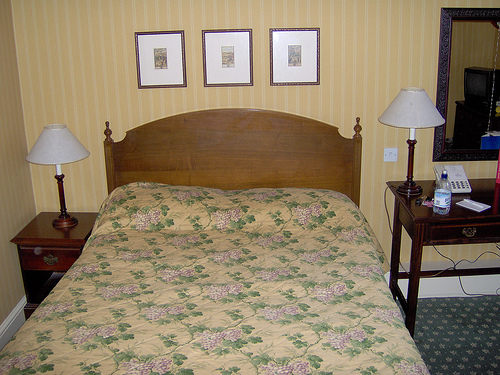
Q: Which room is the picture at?
A: It is at the bedroom.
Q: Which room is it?
A: It is a bedroom.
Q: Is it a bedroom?
A: Yes, it is a bedroom.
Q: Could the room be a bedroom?
A: Yes, it is a bedroom.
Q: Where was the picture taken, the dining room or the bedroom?
A: It was taken at the bedroom.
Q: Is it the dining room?
A: No, it is the bedroom.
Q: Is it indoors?
A: Yes, it is indoors.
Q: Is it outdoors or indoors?
A: It is indoors.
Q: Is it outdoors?
A: No, it is indoors.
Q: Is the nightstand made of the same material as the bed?
A: Yes, both the nightstand and the bed are made of wood.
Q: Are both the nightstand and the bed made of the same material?
A: Yes, both the nightstand and the bed are made of wood.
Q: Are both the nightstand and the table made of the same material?
A: Yes, both the nightstand and the table are made of wood.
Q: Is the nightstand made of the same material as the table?
A: Yes, both the nightstand and the table are made of wood.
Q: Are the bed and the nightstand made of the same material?
A: Yes, both the bed and the nightstand are made of wood.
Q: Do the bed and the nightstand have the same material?
A: Yes, both the bed and the nightstand are made of wood.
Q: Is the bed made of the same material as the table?
A: Yes, both the bed and the table are made of wood.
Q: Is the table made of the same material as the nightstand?
A: Yes, both the table and the nightstand are made of wood.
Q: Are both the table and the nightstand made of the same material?
A: Yes, both the table and the nightstand are made of wood.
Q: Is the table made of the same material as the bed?
A: Yes, both the table and the bed are made of wood.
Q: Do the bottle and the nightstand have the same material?
A: No, the bottle is made of plastic and the nightstand is made of wood.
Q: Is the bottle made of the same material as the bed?
A: No, the bottle is made of plastic and the bed is made of wood.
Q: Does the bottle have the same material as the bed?
A: No, the bottle is made of plastic and the bed is made of wood.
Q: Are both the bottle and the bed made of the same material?
A: No, the bottle is made of plastic and the bed is made of wood.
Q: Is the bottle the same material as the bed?
A: No, the bottle is made of plastic and the bed is made of wood.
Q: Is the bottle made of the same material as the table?
A: No, the bottle is made of plastic and the table is made of wood.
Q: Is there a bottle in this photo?
A: Yes, there is a bottle.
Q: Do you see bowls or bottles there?
A: Yes, there is a bottle.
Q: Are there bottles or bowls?
A: Yes, there is a bottle.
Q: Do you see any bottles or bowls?
A: Yes, there is a bottle.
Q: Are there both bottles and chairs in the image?
A: No, there is a bottle but no chairs.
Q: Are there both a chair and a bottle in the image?
A: No, there is a bottle but no chairs.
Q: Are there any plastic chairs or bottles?
A: Yes, there is a plastic bottle.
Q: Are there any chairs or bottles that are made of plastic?
A: Yes, the bottle is made of plastic.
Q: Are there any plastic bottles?
A: Yes, there is a bottle that is made of plastic.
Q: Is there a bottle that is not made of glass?
A: Yes, there is a bottle that is made of plastic.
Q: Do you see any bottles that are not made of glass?
A: Yes, there is a bottle that is made of plastic.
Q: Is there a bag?
A: No, there are no bags.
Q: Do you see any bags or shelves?
A: No, there are no bags or shelves.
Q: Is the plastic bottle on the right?
A: Yes, the bottle is on the right of the image.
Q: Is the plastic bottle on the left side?
A: No, the bottle is on the right of the image.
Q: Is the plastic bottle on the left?
A: No, the bottle is on the right of the image.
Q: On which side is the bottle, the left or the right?
A: The bottle is on the right of the image.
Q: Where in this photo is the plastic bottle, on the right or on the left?
A: The bottle is on the right of the image.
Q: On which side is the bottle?
A: The bottle is on the right of the image.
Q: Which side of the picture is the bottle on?
A: The bottle is on the right of the image.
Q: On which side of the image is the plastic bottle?
A: The bottle is on the right of the image.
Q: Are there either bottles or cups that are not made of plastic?
A: No, there is a bottle but it is made of plastic.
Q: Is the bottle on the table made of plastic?
A: Yes, the bottle is made of plastic.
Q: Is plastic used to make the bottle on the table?
A: Yes, the bottle is made of plastic.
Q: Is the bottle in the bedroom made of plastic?
A: Yes, the bottle is made of plastic.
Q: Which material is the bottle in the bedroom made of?
A: The bottle is made of plastic.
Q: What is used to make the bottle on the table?
A: The bottle is made of plastic.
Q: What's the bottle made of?
A: The bottle is made of plastic.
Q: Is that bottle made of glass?
A: No, the bottle is made of plastic.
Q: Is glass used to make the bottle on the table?
A: No, the bottle is made of plastic.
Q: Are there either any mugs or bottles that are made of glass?
A: No, there is a bottle but it is made of plastic.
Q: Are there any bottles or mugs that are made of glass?
A: No, there is a bottle but it is made of plastic.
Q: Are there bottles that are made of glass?
A: No, there is a bottle but it is made of plastic.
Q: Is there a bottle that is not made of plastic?
A: No, there is a bottle but it is made of plastic.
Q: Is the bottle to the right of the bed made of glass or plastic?
A: The bottle is made of plastic.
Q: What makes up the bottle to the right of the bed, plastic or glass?
A: The bottle is made of plastic.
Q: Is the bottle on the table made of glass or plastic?
A: The bottle is made of plastic.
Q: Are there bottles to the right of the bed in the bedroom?
A: Yes, there is a bottle to the right of the bed.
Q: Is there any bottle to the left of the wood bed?
A: No, the bottle is to the right of the bed.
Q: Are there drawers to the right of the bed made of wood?
A: No, there is a bottle to the right of the bed.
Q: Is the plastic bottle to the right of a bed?
A: Yes, the bottle is to the right of a bed.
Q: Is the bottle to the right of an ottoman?
A: No, the bottle is to the right of a bed.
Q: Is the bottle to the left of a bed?
A: No, the bottle is to the right of a bed.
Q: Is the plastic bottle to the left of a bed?
A: No, the bottle is to the right of a bed.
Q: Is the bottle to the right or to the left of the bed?
A: The bottle is to the right of the bed.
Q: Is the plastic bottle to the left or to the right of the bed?
A: The bottle is to the right of the bed.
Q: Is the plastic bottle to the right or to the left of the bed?
A: The bottle is to the right of the bed.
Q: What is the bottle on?
A: The bottle is on the table.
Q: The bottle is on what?
A: The bottle is on the table.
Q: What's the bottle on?
A: The bottle is on the table.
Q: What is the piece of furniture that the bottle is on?
A: The piece of furniture is a table.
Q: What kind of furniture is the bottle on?
A: The bottle is on the table.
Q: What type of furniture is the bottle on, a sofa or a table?
A: The bottle is on a table.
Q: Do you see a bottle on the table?
A: Yes, there is a bottle on the table.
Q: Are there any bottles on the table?
A: Yes, there is a bottle on the table.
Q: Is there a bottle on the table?
A: Yes, there is a bottle on the table.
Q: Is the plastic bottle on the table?
A: Yes, the bottle is on the table.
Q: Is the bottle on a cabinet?
A: No, the bottle is on the table.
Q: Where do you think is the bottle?
A: The bottle is in the bedroom.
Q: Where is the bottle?
A: The bottle is in the bedroom.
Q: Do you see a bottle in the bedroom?
A: Yes, there is a bottle in the bedroom.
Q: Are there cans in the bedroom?
A: No, there is a bottle in the bedroom.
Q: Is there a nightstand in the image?
A: Yes, there is a nightstand.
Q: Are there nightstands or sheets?
A: Yes, there is a nightstand.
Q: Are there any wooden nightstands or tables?
A: Yes, there is a wood nightstand.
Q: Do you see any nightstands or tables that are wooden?
A: Yes, the nightstand is wooden.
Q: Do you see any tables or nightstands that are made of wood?
A: Yes, the nightstand is made of wood.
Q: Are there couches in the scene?
A: No, there are no couches.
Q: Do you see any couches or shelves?
A: No, there are no couches or shelves.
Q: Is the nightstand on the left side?
A: Yes, the nightstand is on the left of the image.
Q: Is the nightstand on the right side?
A: No, the nightstand is on the left of the image.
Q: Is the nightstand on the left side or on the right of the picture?
A: The nightstand is on the left of the image.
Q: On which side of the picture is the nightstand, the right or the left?
A: The nightstand is on the left of the image.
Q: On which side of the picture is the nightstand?
A: The nightstand is on the left of the image.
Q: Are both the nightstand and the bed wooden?
A: Yes, both the nightstand and the bed are wooden.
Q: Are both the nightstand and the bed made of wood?
A: Yes, both the nightstand and the bed are made of wood.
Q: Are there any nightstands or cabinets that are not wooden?
A: No, there is a nightstand but it is wooden.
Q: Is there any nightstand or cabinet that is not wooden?
A: No, there is a nightstand but it is wooden.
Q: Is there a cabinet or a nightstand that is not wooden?
A: No, there is a nightstand but it is wooden.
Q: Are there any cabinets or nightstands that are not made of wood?
A: No, there is a nightstand but it is made of wood.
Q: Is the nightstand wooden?
A: Yes, the nightstand is wooden.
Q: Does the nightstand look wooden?
A: Yes, the nightstand is wooden.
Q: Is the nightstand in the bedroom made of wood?
A: Yes, the nightstand is made of wood.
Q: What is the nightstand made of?
A: The nightstand is made of wood.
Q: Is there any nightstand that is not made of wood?
A: No, there is a nightstand but it is made of wood.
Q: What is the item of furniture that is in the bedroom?
A: The piece of furniture is a nightstand.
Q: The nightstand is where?
A: The nightstand is in the bedroom.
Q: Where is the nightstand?
A: The nightstand is in the bedroom.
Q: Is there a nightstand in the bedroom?
A: Yes, there is a nightstand in the bedroom.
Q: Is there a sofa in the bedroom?
A: No, there is a nightstand in the bedroom.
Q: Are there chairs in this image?
A: No, there are no chairs.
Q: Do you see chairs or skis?
A: No, there are no chairs or skis.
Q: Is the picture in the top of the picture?
A: Yes, the picture is in the top of the image.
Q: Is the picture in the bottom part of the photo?
A: No, the picture is in the top of the image.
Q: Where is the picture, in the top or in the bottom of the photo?
A: The picture is in the top of the image.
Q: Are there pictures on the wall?
A: Yes, there is a picture on the wall.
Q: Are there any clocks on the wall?
A: No, there is a picture on the wall.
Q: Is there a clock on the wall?
A: No, there is a picture on the wall.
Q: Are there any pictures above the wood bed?
A: Yes, there is a picture above the bed.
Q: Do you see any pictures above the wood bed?
A: Yes, there is a picture above the bed.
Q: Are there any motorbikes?
A: No, there are no motorbikes.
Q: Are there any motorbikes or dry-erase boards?
A: No, there are no motorbikes or dry-erase boards.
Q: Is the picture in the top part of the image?
A: Yes, the picture is in the top of the image.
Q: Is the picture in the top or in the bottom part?
A: The picture is in the top of the image.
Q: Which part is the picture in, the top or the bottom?
A: The picture is in the top of the image.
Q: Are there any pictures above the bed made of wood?
A: Yes, there is a picture above the bed.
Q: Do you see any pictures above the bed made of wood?
A: Yes, there is a picture above the bed.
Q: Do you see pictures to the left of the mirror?
A: Yes, there is a picture to the left of the mirror.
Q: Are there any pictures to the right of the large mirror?
A: No, the picture is to the left of the mirror.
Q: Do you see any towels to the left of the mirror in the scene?
A: No, there is a picture to the left of the mirror.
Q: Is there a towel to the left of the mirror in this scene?
A: No, there is a picture to the left of the mirror.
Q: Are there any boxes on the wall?
A: No, there is a picture on the wall.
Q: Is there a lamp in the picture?
A: Yes, there is a lamp.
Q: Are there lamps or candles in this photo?
A: Yes, there is a lamp.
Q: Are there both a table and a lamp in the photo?
A: Yes, there are both a lamp and a table.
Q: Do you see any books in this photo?
A: No, there are no books.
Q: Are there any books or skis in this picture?
A: No, there are no books or skis.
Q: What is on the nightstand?
A: The lamp is on the nightstand.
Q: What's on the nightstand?
A: The lamp is on the nightstand.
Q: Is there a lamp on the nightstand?
A: Yes, there is a lamp on the nightstand.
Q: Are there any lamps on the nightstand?
A: Yes, there is a lamp on the nightstand.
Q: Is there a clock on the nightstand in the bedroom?
A: No, there is a lamp on the nightstand.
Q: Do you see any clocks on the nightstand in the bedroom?
A: No, there is a lamp on the nightstand.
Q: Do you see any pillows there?
A: No, there are no pillows.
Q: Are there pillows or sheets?
A: No, there are no pillows or sheets.